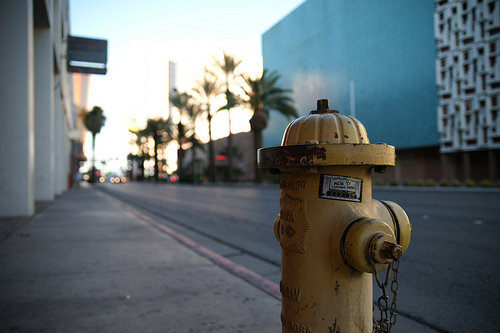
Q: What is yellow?
A: Hydrant.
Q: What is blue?
A: Building.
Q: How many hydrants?
A: One.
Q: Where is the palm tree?
A: On the right.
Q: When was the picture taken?
A: Daytime.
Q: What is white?
A: Building on the left.